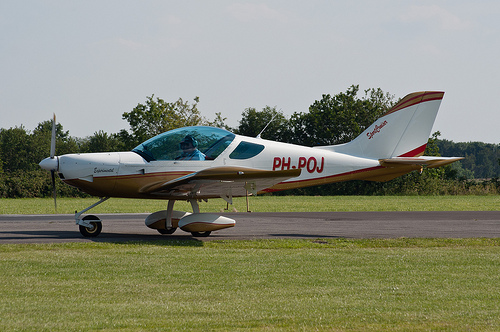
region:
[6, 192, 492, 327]
strips of green grass on sides of gray paved road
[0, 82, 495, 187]
bushes and plants growing behind plane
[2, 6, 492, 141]
clear light blue sky overhead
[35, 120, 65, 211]
propeller on front of plane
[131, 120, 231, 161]
curved blue bubble over cockpit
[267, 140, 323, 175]
red letters on side of white plane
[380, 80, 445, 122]
gold and red curves over tail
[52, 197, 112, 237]
slanted support over wheel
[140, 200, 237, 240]
tan and white ovals over rear wheels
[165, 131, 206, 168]
seated pilot in plane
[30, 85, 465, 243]
a small white plane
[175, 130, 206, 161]
a person in the cockpit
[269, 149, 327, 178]
letters on the side of the plane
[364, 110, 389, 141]
writing on the tail of the plane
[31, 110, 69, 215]
propellor on the front of the plane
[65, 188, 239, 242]
landing gear of the plane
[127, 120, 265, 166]
windows on the plane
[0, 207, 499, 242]
a gray asphalt runway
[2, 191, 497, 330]
mowed grass on either side of the runway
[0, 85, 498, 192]
a row of trees behind the field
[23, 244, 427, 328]
green grass growing by runway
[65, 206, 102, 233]
landing gear of plane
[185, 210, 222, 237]
landing gear of plane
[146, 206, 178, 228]
landing gear of plane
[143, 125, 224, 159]
glass cockpit of plane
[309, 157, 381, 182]
red stripe on plane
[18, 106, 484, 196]
trees growing by runway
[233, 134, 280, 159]
small window on plane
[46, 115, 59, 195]
propeller on front of plane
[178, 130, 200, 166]
pilot sitting in cockpit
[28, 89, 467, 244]
This is a small plane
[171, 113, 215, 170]
The pilot is in the plane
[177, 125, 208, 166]
The pilot is wearing headphones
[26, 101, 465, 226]
The plane is not moving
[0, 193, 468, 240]
The plane is on pavement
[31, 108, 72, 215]
Propeller on the front of the plane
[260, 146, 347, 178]
Plane says PH-POJ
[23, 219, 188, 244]
Plane casting shadows on the ground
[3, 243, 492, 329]
Large grassy area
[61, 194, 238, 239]
The plane has three wheels